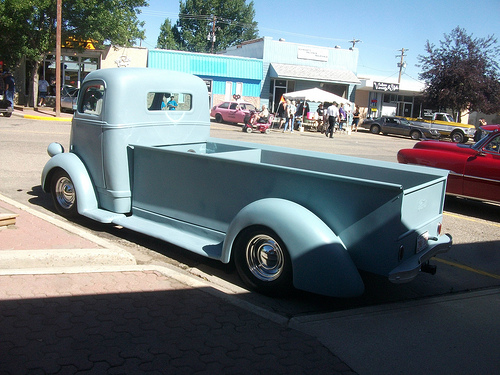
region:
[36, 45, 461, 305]
the car is light blue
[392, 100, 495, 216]
the car is red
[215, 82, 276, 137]
the car is pink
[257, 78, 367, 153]
people walking towards canopy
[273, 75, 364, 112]
the canopy is white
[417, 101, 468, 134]
the car is yellow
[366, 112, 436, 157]
the car is gray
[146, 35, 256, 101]
the building is blue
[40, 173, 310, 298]
tires are black and silver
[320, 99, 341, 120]
man's shirt is white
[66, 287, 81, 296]
edge of a shade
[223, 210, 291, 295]
part of a wheel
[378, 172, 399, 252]
edge of a truck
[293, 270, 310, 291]
edge of a guard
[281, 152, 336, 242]
part of a truck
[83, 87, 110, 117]
part of a window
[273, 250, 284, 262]
part of a wheel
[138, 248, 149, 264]
edge of a road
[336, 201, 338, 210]
back of a car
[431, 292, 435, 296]
part of the road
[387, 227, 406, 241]
back of a car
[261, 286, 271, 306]
branches of a tree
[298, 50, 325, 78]
part of a building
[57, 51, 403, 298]
the truck is pale blue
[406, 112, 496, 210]
the car is red in color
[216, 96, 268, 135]
the car is pink in color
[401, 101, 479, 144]
the truck is yellow and white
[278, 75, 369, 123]
the tent is white in color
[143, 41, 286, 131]
the building is blue and white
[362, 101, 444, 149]
the car is grey in color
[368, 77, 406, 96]
the sign is black and white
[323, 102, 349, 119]
the shirt is white in color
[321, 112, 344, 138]
the pants are black in color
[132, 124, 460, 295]
long blue bed in truck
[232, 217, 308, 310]
black wheel on truck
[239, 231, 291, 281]
shiny chrome hubcap on wheel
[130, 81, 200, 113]
rectangular rear window in truck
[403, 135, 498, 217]
red car next to blue truck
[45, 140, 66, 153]
round headlight on blue truck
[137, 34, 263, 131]
blue awning on building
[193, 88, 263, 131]
pink car near building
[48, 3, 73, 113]
tall brown pole left of building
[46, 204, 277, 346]
white line near truck